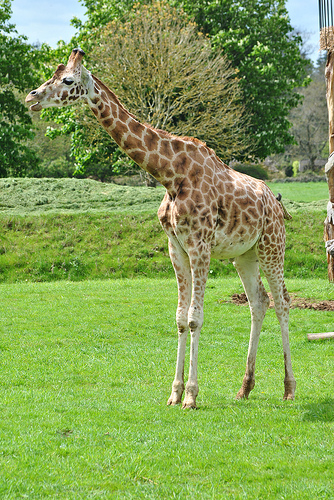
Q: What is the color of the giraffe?
A: Brown.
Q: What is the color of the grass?
A: Green.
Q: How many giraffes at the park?
A: One.